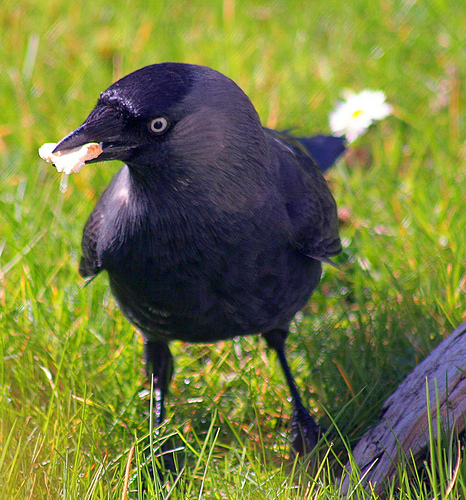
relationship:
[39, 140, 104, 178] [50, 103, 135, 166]
bread in beak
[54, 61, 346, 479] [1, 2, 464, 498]
bird standing on grass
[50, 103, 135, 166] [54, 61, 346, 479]
beak on bird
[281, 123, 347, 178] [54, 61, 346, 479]
tailfeathers on bird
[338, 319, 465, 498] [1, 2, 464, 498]
branch on grass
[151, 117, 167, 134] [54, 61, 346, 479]
eye of bird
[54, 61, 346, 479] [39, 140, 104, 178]
bird eating bread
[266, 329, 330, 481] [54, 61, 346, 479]
feet on bird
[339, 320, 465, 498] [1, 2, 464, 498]
log on grass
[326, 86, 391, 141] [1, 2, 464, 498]
flower on grass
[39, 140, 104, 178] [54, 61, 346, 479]
bread in mouth of bird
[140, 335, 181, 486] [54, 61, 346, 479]
leg of bird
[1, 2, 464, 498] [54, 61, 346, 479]
grass beneath bird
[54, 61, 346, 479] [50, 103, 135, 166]
bird with bread in beak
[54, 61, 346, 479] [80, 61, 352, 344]
bird with black feathers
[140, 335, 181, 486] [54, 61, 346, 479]
leg on bird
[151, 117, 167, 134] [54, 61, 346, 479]
eye on bird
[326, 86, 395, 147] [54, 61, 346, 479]
flower behind bird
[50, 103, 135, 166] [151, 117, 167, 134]
beak near eye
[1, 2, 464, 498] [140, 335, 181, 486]
grass below leg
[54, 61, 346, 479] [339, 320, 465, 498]
bird next to log